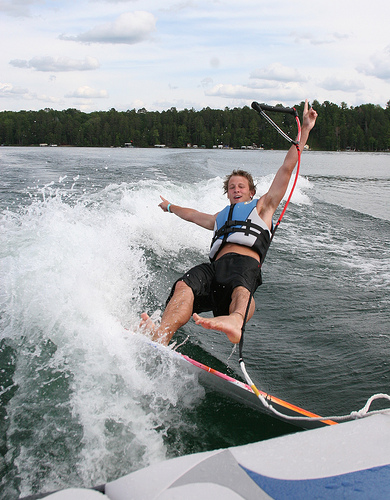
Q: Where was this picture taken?
A: A lake.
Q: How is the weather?
A: Clear.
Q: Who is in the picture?
A: A man.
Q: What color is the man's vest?
A: Blue.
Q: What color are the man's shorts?
A: Black.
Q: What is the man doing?
A: Waterboarding.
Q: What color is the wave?
A: White.